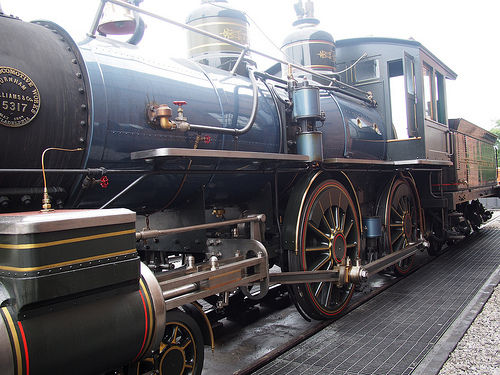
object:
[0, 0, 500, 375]
train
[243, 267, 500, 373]
floor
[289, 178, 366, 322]
wheel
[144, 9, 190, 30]
metal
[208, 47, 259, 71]
engine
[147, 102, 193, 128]
bell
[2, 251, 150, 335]
piston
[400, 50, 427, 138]
door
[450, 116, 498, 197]
car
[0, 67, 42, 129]
nameplate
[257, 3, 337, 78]
stock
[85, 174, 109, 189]
handle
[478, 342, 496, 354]
gravel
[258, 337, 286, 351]
track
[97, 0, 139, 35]
tank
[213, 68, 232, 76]
fuel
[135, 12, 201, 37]
pipe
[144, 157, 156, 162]
bolt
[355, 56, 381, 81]
window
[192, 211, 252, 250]
rivet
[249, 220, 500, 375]
walkway